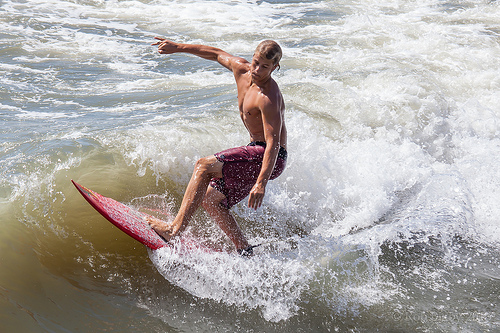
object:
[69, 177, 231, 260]
sufboard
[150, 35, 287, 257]
man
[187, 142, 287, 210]
trunks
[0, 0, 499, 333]
waves